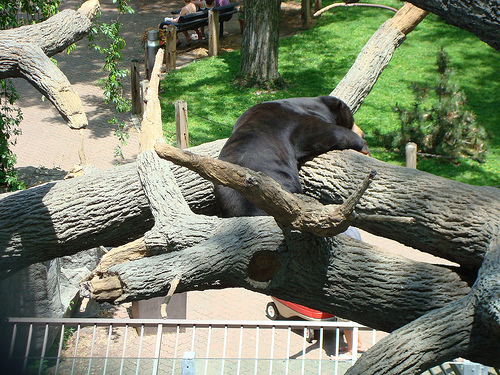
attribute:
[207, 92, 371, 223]
animal — black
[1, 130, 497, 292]
branch — tree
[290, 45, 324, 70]
grass — green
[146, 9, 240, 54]
bench — wooden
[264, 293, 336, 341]
wagon — toy, red, beige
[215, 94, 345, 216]
fur — black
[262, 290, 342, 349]
wagon — little, red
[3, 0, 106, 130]
tree branch — very big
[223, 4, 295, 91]
trunk — big, tree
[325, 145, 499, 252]
tree branch — twisted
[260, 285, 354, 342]
wagon — red, brown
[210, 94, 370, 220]
bear — black